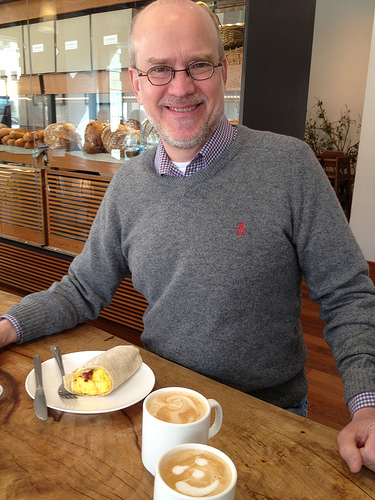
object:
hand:
[336, 401, 375, 475]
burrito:
[62, 345, 142, 396]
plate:
[24, 351, 155, 414]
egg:
[72, 368, 112, 395]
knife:
[34, 354, 48, 421]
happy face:
[170, 456, 220, 498]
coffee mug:
[152, 443, 238, 498]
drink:
[160, 447, 231, 496]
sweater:
[0, 124, 374, 406]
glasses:
[130, 59, 224, 86]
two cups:
[141, 387, 238, 499]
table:
[1, 293, 373, 497]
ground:
[177, 49, 201, 68]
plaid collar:
[154, 112, 237, 178]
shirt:
[1, 118, 374, 415]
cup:
[140, 386, 224, 477]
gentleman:
[0, 0, 375, 476]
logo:
[235, 222, 248, 237]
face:
[130, 0, 225, 149]